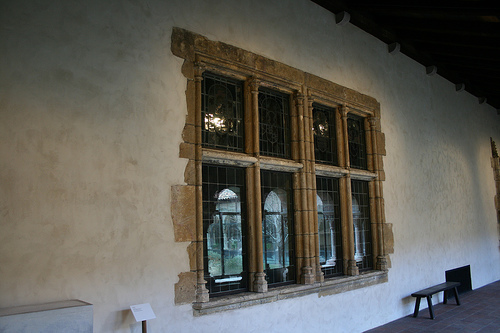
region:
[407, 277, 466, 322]
bench next to the wall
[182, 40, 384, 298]
large window with wooden outside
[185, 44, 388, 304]
eight windows with reflections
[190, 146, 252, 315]
part of a window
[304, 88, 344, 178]
part of a window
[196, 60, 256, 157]
part of a window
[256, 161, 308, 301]
part of a window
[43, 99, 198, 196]
part of a wall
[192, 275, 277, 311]
part of a window sill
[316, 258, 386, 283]
part of a window sill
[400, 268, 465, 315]
Bench against the wall.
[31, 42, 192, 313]
The wall is off white.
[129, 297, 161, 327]
The tag is white.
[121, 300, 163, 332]
Tag on a pole.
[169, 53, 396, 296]
There are eight connected windows panes.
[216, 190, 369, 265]
A building is visible from the bottom windows.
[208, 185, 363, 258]
The building is white.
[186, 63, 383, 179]
The top windows are black.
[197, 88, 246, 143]
Light shining on the window.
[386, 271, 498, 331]
The floor is brick.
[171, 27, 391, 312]
A brown concrete window frame with 8 windows inside.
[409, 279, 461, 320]
A black bench with four legs and no back.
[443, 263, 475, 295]
A rectangle hole in the wall beside a bench.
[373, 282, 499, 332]
A dark brick walkway.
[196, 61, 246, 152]
Top window with brightest white glare in it.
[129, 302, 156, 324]
A white note on a pole.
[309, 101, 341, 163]
Top third window from the left.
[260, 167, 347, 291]
The two bottom middle windows.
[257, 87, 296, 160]
More visible totally black window with no glare.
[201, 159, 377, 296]
All four bottom windows.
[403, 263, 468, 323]
A small bench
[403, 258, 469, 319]
The bench is against the wall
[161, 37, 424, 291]
Huge window on the wall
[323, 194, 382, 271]
Two pillars visible through the window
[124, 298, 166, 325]
A small white sign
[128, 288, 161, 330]
Sign on a narrow wooden post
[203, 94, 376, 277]
The windows are closed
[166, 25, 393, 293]
windows in a building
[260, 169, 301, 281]
a glass pane in a window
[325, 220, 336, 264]
a stone column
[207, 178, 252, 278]
a reflection in a window pane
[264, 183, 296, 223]
a stone archway on a building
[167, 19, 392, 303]
a brown stone window casement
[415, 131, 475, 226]
a white stucco wall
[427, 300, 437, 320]
a wooden leg painted black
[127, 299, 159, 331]
an information plaque on a post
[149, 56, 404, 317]
4 large windows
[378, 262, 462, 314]
A chair next to the wall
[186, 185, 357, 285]
Reflections in the window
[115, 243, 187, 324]
A little plaque by the Windows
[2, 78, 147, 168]
A brick wall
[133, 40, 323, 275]
Rock around the window seal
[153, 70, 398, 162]
For small windows on top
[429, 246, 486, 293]
A black square next to the floor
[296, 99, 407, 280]
Brown trim around the windows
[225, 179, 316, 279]
Reflection of the tree